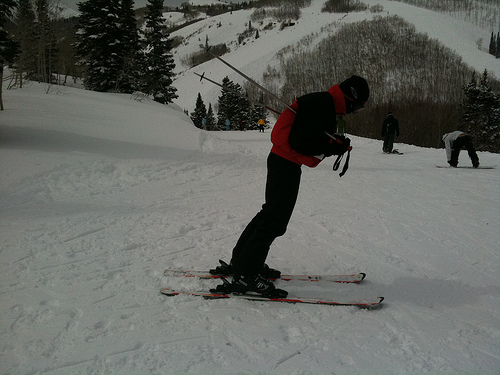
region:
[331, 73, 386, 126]
a black ski mask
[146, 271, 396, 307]
red and white skis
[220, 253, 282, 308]
black and white ski boots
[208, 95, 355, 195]
red and black jacket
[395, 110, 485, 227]
a person bending down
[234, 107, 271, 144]
a person in a yellow jacket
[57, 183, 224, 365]
ski tracks in the snow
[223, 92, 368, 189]
two ski poles with straps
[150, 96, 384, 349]
person leaning on skis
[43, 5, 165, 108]
green trees with snow on them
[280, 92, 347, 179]
The ski jacket is red and black.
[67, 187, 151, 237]
The snow is white.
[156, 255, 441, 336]
The man is wearing skis.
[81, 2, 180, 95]
The trees on left are pine trees.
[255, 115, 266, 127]
A skier has a yellow ski jacket.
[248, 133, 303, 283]
The skier has black ski pants on.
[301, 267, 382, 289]
Snow is on top of the skis.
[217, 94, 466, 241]
The skier's are going downhill.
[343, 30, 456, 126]
No leaves on the trees.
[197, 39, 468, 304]
The weather is cloudy and cold.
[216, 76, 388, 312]
a man standing on a pair of skis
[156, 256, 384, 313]
red skis covered with snow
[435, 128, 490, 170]
a man on a snow board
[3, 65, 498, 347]
a snow covered mountain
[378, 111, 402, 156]
a person standing in the snow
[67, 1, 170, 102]
a group of trees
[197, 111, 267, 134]
several people standing in the snow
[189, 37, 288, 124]
a set of ski poles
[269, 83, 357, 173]
a black and red ski jacket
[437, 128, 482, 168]
a person in a gray jacket and black pants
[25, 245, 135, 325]
The snow is white.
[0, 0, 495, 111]
Mountains are in the background.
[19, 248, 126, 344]
Snow is on the ground.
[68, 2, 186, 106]
Snow is on the trees.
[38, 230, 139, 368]
The snow has tracks in it.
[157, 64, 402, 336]
The person is skiing.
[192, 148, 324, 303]
The person is wearing black pants.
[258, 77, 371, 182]
The person is wearing a red top.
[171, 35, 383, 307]
The person is holding ski poles.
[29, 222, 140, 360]
The snow is thick.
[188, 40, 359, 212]
skier holding ski poles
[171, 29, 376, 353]
skier in winter clothes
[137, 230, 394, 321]
red and white skis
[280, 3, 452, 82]
ski slope covered with trees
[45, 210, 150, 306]
ski tracks in snow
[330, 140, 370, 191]
wrist straps for ski poles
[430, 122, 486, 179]
snowboarder strapping board to feet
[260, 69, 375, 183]
skier wearing red and black coat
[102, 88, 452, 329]
skiers and snowboarders on slope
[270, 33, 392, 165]
skier wearing black hat